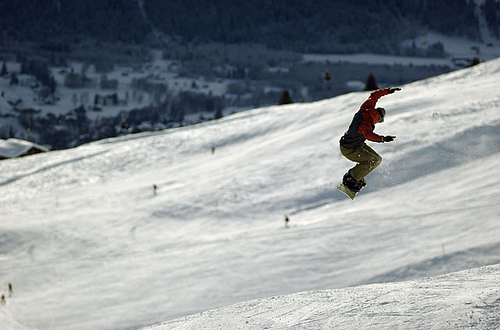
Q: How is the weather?
A: Sunny.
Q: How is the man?
A: In the air.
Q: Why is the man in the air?
A: He went off a jump.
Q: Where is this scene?
A: A mountain.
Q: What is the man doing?
A: Snowboarding.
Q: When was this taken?
A: Day time.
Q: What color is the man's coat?
A: Red.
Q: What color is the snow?
A: White.